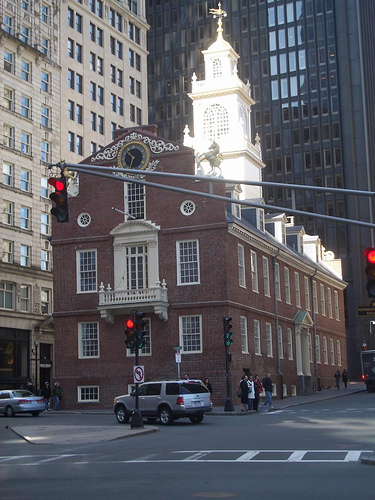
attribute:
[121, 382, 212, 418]
car — grey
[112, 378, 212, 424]
car — grey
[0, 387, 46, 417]
car — grey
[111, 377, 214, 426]
suv — grey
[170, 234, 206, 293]
window — white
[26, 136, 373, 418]
building — red, brick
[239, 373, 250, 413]
woman — black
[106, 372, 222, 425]
car — grey